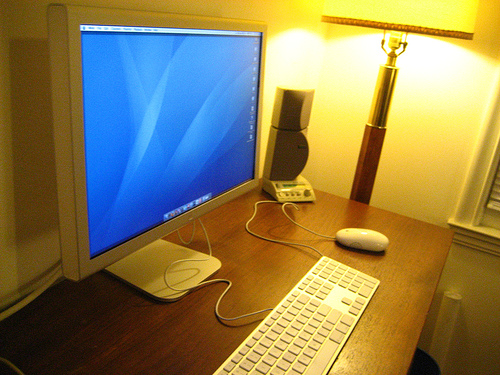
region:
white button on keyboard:
[237, 355, 253, 370]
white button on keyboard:
[245, 352, 260, 362]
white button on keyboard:
[250, 342, 265, 354]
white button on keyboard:
[265, 327, 276, 338]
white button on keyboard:
[253, 360, 273, 372]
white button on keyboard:
[260, 352, 275, 363]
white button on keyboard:
[265, 342, 281, 357]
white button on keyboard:
[278, 332, 291, 342]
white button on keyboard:
[275, 355, 290, 367]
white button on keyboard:
[288, 343, 300, 356]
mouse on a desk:
[327, 221, 402, 252]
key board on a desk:
[256, 257, 366, 370]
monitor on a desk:
[41, 2, 246, 287]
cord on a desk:
[212, 273, 238, 328]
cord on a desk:
[276, 232, 313, 257]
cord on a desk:
[240, 195, 257, 235]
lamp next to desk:
[335, 37, 395, 202]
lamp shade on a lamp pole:
[371, 1, 482, 34]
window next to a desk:
[450, 151, 490, 243]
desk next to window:
[407, 211, 449, 311]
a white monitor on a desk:
[47, 7, 267, 279]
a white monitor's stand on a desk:
[106, 238, 223, 300]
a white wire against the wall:
[1, 265, 58, 321]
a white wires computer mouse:
[336, 225, 388, 247]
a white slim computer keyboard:
[213, 255, 379, 373]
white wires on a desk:
[162, 200, 336, 321]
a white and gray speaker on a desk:
[262, 83, 314, 203]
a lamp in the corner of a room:
[321, 3, 479, 205]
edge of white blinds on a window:
[488, 162, 499, 218]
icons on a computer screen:
[246, 44, 260, 143]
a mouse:
[332, 217, 399, 259]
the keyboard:
[252, 338, 326, 368]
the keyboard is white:
[270, 305, 343, 351]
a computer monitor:
[71, 37, 275, 189]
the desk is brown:
[90, 316, 182, 359]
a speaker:
[272, 90, 309, 184]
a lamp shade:
[415, 5, 470, 34]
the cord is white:
[207, 290, 242, 323]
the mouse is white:
[328, 220, 398, 257]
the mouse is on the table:
[332, 226, 391, 252]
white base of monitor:
[92, 241, 215, 321]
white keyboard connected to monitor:
[263, 300, 285, 328]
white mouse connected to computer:
[342, 226, 390, 275]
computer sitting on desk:
[423, 236, 434, 283]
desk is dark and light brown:
[80, 330, 133, 356]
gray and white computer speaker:
[271, 95, 316, 198]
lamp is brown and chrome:
[343, 110, 388, 205]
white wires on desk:
[246, 202, 283, 279]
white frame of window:
[453, 179, 478, 255]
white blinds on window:
[486, 195, 493, 216]